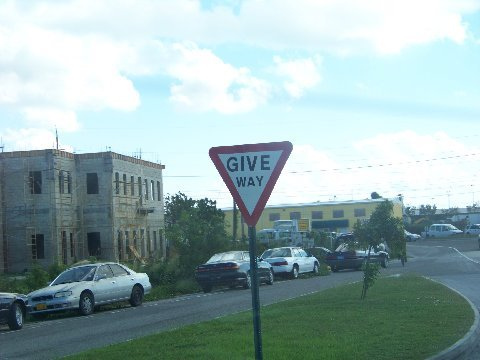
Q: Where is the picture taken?
A: The road.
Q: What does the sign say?
A: GIVE WAY.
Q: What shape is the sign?
A: Triangle.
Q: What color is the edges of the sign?
A: Red.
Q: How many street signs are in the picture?
A: One.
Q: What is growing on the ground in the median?
A: Grass.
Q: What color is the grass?
A: Green.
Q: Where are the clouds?
A: The sky.